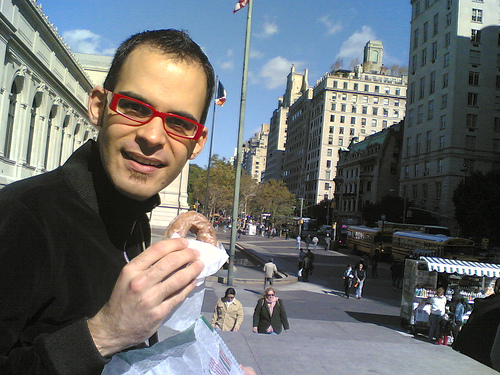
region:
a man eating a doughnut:
[48, 35, 243, 350]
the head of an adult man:
[81, 21, 221, 211]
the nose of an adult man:
[135, 112, 172, 153]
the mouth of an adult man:
[108, 145, 169, 177]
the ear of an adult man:
[72, 76, 106, 120]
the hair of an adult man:
[121, 29, 202, 71]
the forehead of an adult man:
[130, 56, 215, 106]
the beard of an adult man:
[122, 166, 154, 198]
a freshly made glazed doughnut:
[155, 206, 220, 266]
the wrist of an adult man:
[84, 282, 161, 356]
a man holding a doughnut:
[68, 18, 235, 345]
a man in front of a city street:
[58, 23, 413, 327]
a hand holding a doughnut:
[133, 208, 220, 314]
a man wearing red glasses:
[84, 24, 212, 211]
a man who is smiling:
[84, 20, 211, 212]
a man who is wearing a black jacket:
[3, 8, 198, 368]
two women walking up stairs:
[207, 275, 308, 338]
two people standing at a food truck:
[401, 253, 481, 339]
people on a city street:
[248, 230, 378, 300]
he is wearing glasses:
[109, 95, 197, 144]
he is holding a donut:
[166, 224, 205, 259]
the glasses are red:
[115, 96, 157, 128]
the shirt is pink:
[266, 302, 276, 313]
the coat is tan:
[221, 308, 236, 323]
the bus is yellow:
[396, 239, 408, 254]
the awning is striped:
[437, 259, 464, 271]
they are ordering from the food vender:
[433, 285, 467, 303]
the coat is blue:
[455, 308, 463, 316]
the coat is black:
[271, 311, 281, 322]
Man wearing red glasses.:
[89, 26, 216, 203]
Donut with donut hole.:
[148, 206, 225, 286]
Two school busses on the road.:
[340, 218, 482, 278]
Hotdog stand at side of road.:
[399, 251, 498, 342]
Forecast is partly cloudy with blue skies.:
[99, 0, 407, 50]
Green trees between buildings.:
[192, 159, 292, 236]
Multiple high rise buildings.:
[239, 5, 494, 230]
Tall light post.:
[227, 0, 256, 281]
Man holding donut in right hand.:
[5, 9, 249, 374]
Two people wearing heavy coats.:
[210, 283, 294, 339]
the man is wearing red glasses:
[89, 79, 211, 165]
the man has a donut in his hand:
[83, 73, 236, 294]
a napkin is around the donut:
[157, 211, 225, 285]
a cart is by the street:
[393, 250, 498, 347]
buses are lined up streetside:
[243, 195, 495, 288]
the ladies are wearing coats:
[209, 282, 292, 341]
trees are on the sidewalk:
[192, 159, 299, 246]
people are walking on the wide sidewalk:
[221, 203, 416, 310]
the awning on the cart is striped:
[406, 250, 498, 296]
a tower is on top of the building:
[310, 33, 406, 90]